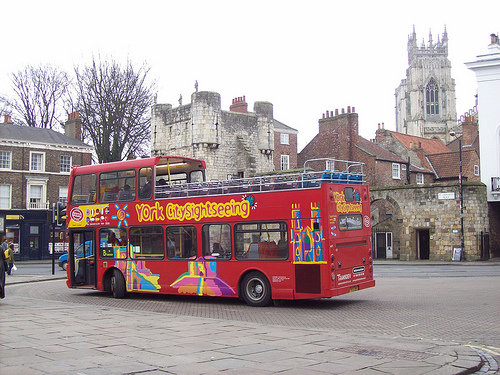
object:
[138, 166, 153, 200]
windows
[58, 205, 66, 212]
traffic light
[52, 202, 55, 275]
pole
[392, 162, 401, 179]
window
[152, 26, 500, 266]
building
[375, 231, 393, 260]
door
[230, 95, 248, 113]
chimney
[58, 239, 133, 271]
car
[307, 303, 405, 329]
street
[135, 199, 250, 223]
sign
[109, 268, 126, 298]
front wheel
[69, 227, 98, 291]
access door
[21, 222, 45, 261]
front door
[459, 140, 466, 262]
pole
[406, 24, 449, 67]
tower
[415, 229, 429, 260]
door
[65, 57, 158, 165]
tree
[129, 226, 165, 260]
windows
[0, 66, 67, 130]
trees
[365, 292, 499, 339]
pavers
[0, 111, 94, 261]
building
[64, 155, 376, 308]
bus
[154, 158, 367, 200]
deck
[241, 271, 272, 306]
tire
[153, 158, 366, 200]
rail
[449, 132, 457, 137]
street light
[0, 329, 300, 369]
sidewalk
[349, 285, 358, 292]
license plate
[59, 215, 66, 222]
traffic light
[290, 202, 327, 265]
castle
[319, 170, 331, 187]
seats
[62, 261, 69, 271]
tire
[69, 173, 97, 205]
windows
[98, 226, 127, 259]
windows